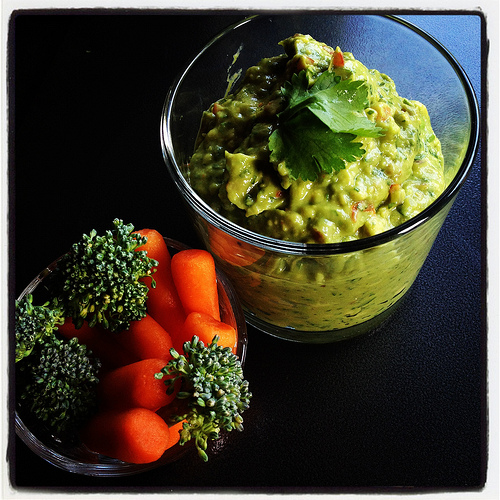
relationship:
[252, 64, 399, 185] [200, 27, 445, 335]
garnish on top of guacamole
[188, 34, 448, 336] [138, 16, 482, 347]
guacamole in bowl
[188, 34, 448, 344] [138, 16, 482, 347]
guacamole sitting in bowl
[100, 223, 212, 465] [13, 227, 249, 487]
baby carrots in small bowl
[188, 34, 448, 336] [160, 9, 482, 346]
guacamole inside bowl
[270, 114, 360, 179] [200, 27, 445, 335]
leaf on top of guacamole